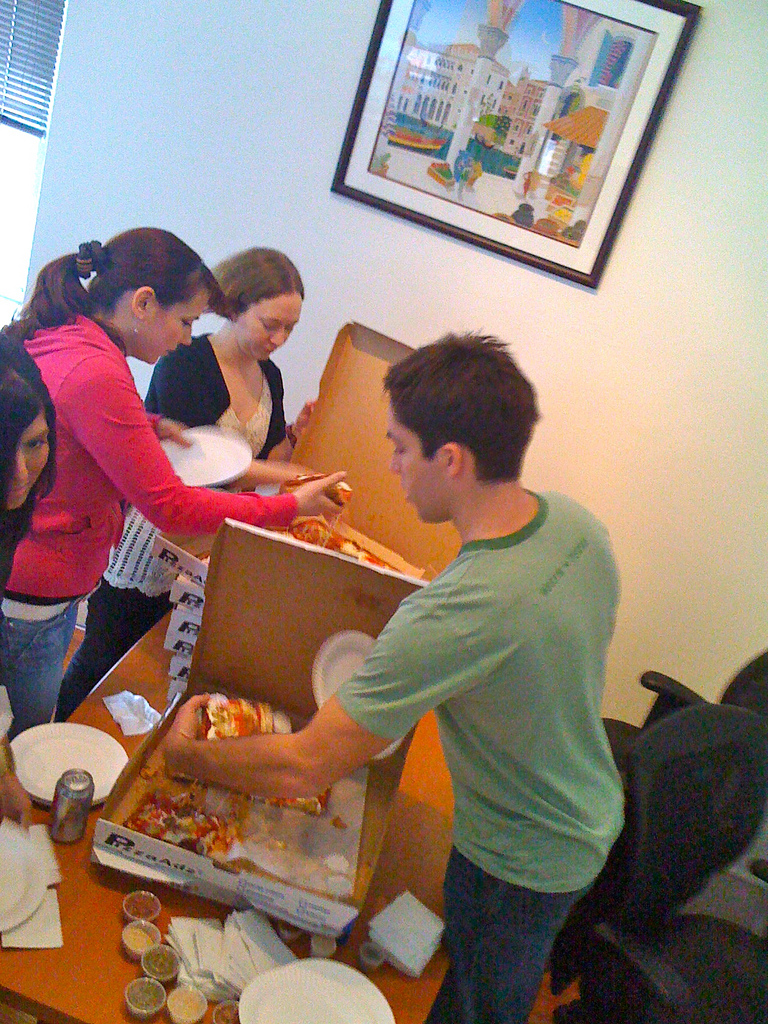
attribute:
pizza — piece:
[170, 657, 309, 862]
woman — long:
[10, 335, 100, 679]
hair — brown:
[1, 322, 62, 539]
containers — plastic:
[92, 890, 263, 1012]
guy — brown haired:
[268, 298, 668, 1000]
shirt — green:
[296, 518, 675, 910]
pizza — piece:
[145, 657, 348, 837]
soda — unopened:
[39, 763, 140, 880]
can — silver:
[29, 747, 121, 879]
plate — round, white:
[156, 420, 271, 517]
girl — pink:
[19, 192, 335, 736]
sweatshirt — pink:
[8, 294, 331, 623]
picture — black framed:
[346, 13, 714, 363]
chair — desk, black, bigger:
[572, 636, 760, 972]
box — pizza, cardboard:
[107, 508, 465, 971]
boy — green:
[329, 300, 675, 928]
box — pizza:
[113, 460, 438, 964]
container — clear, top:
[99, 874, 205, 1010]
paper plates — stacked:
[244, 965, 390, 1016]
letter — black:
[533, 568, 562, 591]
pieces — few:
[175, 776, 282, 845]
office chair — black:
[583, 702, 746, 996]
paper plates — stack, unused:
[199, 952, 372, 1020]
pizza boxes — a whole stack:
[149, 546, 195, 714]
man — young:
[348, 338, 618, 971]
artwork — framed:
[340, 0, 703, 300]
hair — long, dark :
[6, 337, 60, 585]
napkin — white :
[169, 908, 283, 994]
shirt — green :
[333, 485, 631, 891]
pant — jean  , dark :
[432, 833, 599, 1020]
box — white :
[94, 521, 443, 935]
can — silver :
[50, 767, 93, 845]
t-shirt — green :
[330, 479, 630, 897]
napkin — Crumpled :
[102, 687, 163, 734]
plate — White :
[11, 721, 128, 804]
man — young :
[159, 333, 623, 1022]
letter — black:
[549, 570, 557, 583]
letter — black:
[555, 561, 568, 581]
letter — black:
[571, 540, 582, 556]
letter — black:
[564, 547, 583, 570]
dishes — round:
[112, 882, 241, 1021]